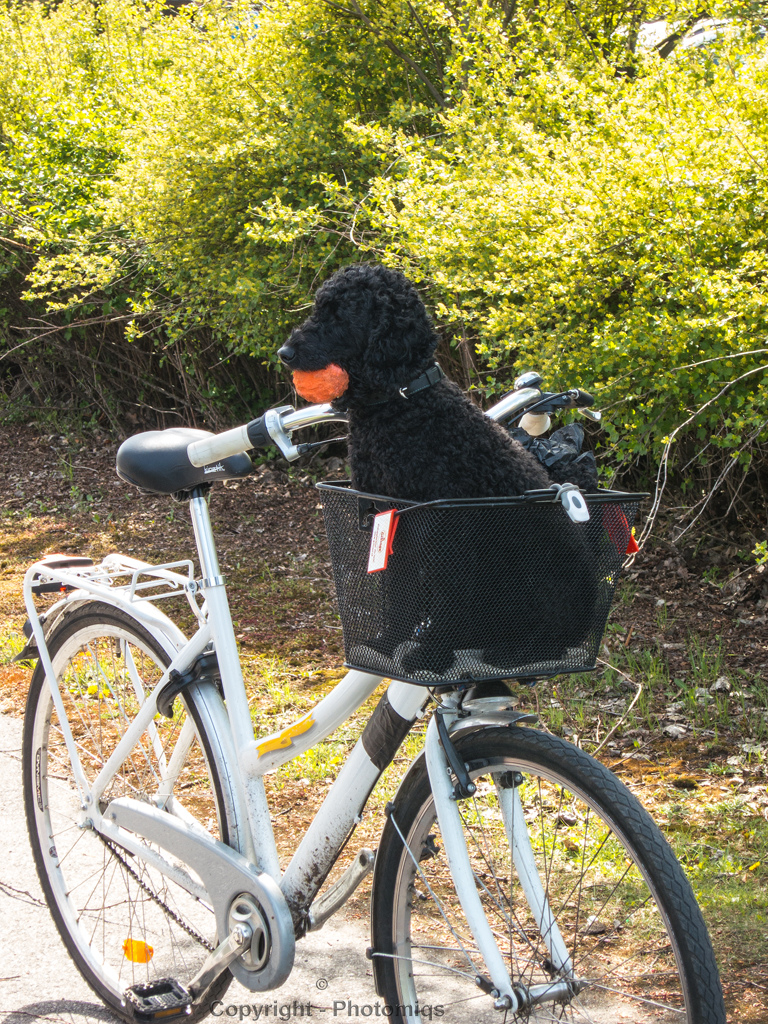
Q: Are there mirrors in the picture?
A: No, there are no mirrors.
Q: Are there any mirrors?
A: No, there are no mirrors.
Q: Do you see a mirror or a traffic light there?
A: No, there are no mirrors or traffic lights.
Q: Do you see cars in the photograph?
A: No, there are no cars.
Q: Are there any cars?
A: No, there are no cars.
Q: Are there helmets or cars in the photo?
A: No, there are no cars or helmets.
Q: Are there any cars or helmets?
A: No, there are no cars or helmets.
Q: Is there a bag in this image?
A: No, there are no bags.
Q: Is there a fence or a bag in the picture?
A: No, there are no bags or fences.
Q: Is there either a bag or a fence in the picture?
A: No, there are no bags or fences.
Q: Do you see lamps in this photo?
A: No, there are no lamps.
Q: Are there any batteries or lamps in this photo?
A: No, there are no lamps or batteries.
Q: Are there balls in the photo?
A: Yes, there is a ball.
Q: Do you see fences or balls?
A: Yes, there is a ball.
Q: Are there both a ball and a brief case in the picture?
A: No, there is a ball but no briefcases.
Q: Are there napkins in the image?
A: No, there are no napkins.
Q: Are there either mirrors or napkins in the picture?
A: No, there are no napkins or mirrors.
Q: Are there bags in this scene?
A: No, there are no bags.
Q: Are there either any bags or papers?
A: No, there are no bags or papers.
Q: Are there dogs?
A: Yes, there is a dog.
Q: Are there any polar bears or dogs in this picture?
A: Yes, there is a dog.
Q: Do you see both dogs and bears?
A: No, there is a dog but no bears.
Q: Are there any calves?
A: No, there are no calves.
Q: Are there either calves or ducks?
A: No, there are no calves or ducks.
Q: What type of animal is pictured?
A: The animal is a dog.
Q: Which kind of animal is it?
A: The animal is a dog.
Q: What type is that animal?
A: That is a dog.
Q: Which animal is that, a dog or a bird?
A: That is a dog.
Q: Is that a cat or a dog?
A: That is a dog.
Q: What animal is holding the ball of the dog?
A: The animal is a dog.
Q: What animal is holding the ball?
A: The animal is a dog.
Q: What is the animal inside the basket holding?
A: The dog is holding the ball.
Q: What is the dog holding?
A: The dog is holding the ball.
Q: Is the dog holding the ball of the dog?
A: Yes, the dog is holding the ball.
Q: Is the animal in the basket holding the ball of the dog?
A: Yes, the dog is holding the ball.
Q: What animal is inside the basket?
A: The dog is inside the basket.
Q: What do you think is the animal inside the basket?
A: The animal is a dog.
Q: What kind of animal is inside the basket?
A: The animal is a dog.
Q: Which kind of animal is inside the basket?
A: The animal is a dog.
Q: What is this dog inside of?
A: The dog is inside the basket.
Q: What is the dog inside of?
A: The dog is inside the basket.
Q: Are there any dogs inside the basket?
A: Yes, there is a dog inside the basket.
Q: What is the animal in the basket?
A: The animal is a dog.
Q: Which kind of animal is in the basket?
A: The animal is a dog.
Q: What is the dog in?
A: The dog is in the basket.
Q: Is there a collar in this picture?
A: Yes, there is a collar.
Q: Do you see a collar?
A: Yes, there is a collar.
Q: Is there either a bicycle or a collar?
A: Yes, there is a collar.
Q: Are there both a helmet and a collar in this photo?
A: No, there is a collar but no helmets.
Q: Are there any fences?
A: No, there are no fences.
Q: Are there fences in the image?
A: No, there are no fences.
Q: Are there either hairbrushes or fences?
A: No, there are no fences or hairbrushes.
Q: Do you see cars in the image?
A: No, there are no cars.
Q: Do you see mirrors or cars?
A: No, there are no cars or mirrors.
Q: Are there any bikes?
A: Yes, there is a bike.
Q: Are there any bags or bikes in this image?
A: Yes, there is a bike.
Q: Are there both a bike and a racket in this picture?
A: No, there is a bike but no rackets.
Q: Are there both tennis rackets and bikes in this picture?
A: No, there is a bike but no rackets.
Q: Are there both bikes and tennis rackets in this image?
A: No, there is a bike but no rackets.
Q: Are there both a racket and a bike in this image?
A: No, there is a bike but no rackets.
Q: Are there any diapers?
A: No, there are no diapers.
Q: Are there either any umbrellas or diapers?
A: No, there are no diapers or umbrellas.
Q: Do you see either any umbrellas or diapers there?
A: No, there are no diapers or umbrellas.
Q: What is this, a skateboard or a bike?
A: This is a bike.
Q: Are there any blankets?
A: Yes, there is a blanket.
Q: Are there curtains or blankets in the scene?
A: Yes, there is a blanket.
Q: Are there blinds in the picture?
A: No, there are no blinds.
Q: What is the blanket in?
A: The blanket is in the basket.